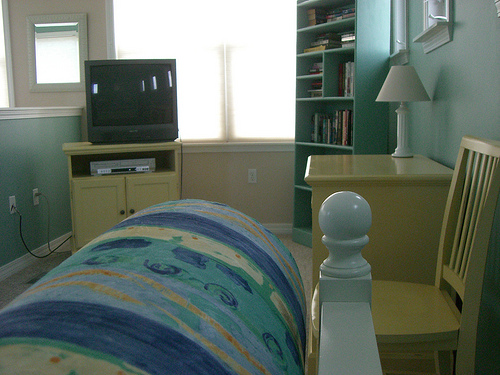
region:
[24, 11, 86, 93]
mirror with a wooden frame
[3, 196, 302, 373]
large blue-patterned blanket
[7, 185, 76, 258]
two wall outlets with wires plugged into them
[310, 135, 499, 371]
yellow chair with slat back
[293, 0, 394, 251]
bookcase full of books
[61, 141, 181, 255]
yellow painted television stand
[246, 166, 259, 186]
empty electrical outlet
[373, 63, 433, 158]
white lamp with white shade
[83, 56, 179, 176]
DVD player and television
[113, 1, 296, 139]
uncurtained window with glare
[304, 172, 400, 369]
wooding white painted pole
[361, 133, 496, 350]
light wood beige chair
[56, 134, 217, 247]
light wood TV stand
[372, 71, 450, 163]
small white and pastel pink lamp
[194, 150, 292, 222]
pastel pink wall color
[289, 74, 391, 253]
green book shelving furniture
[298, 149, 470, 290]
light wood shiny dresser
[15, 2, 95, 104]
white framed mirror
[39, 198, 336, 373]
blue comforter with patterns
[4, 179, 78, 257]
2 outlets with black cords hanging out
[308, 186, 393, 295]
bed post has knob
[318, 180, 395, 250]
Bed knob is white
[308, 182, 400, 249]
Bed knob is round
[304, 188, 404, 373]
Bed frame is white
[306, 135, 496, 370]
Bedroom has green chair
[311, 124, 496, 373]
Green chair is wooden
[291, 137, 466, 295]
Bedroom has green dresser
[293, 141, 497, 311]
Green dresser matches chair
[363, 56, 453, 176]
Dresser has a lamp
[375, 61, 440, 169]
Bedroom lamp is white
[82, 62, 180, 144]
black TV that is not turned on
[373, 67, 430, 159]
white lamp with white lampshade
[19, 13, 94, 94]
white-framed mirror on wall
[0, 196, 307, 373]
arm of couch with blue, yellow, orange, and green pattern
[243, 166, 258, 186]
electrical outlet on wall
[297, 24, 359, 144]
books on shelf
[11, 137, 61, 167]
wall that has been painted green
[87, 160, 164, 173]
DVD/VCR combo machine on shelf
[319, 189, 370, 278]
white post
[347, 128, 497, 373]
wooden chair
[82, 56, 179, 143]
black television on stand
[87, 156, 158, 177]
silver VCR under television set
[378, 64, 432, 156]
white lamp on wood dresser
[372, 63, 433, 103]
white lampshade on lamp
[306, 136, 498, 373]
wooden chair next to dresser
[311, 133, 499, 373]
chair is made of light wood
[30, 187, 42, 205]
white plastic outlet cover on wall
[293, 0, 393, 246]
tall green bookcase in room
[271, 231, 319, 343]
carpeting is beige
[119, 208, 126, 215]
black knob on cabinet